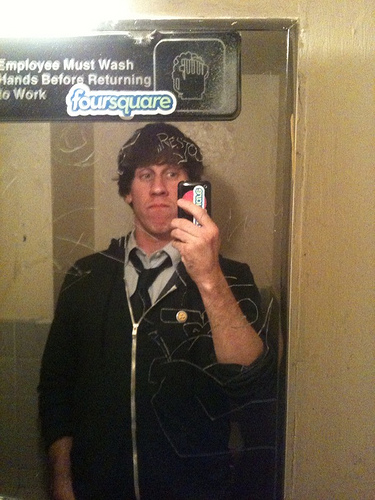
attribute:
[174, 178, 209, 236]
phone — here, cell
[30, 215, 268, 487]
sweater — zippered, black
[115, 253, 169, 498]
zipper — metal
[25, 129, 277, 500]
man — black, here, standing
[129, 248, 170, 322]
tie — black, here, loose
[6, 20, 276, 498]
mirror — here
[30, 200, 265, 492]
jacket — here, zippered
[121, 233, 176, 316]
shirt — gray, grey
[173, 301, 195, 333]
button — here, metal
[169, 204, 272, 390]
arm — here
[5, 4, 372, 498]
bathroom — here